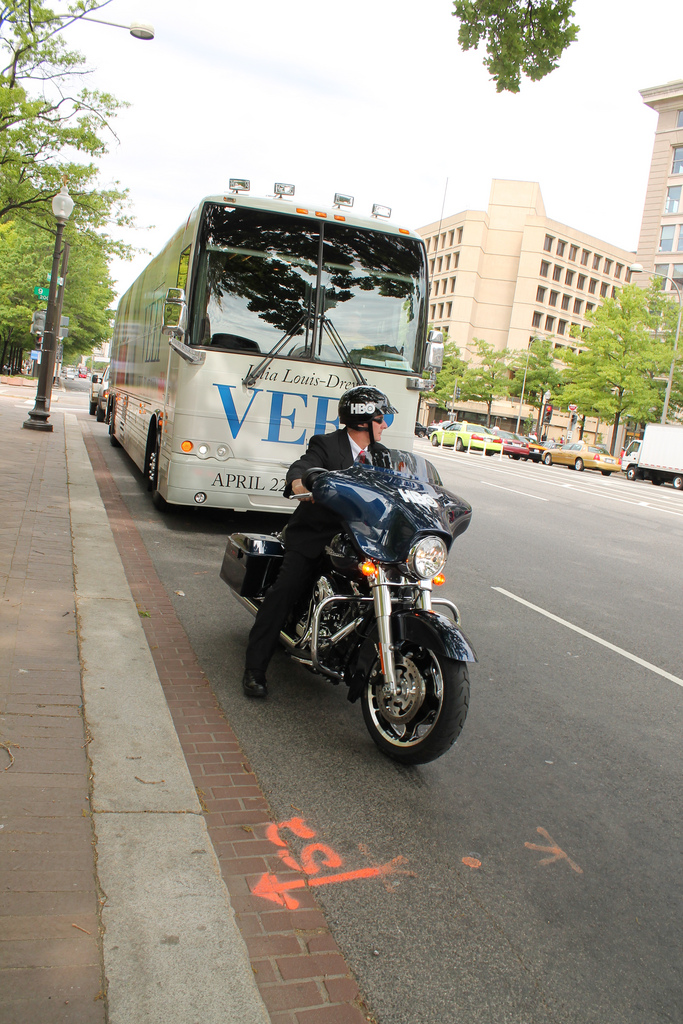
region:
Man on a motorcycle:
[219, 383, 477, 766]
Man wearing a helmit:
[243, 386, 399, 699]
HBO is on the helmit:
[335, 386, 397, 428]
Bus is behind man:
[107, 176, 443, 693]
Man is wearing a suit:
[239, 388, 398, 698]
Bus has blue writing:
[107, 177, 449, 518]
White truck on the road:
[66, 379, 676, 1021]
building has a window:
[545, 232, 556, 256]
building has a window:
[528, 307, 541, 328]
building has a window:
[540, 308, 557, 330]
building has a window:
[552, 316, 566, 330]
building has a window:
[538, 284, 546, 306]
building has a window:
[547, 287, 561, 308]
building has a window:
[557, 292, 571, 310]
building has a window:
[576, 299, 585, 318]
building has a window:
[574, 269, 586, 293]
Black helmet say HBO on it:
[334, 382, 395, 429]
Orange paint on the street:
[241, 798, 592, 922]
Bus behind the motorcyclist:
[94, 171, 434, 520]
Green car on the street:
[437, 421, 505, 458]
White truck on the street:
[612, 412, 682, 492]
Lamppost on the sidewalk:
[19, 174, 87, 438]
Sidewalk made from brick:
[0, 398, 115, 1022]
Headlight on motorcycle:
[408, 528, 457, 587]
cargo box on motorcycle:
[209, 527, 289, 592]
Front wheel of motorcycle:
[350, 622, 476, 768]